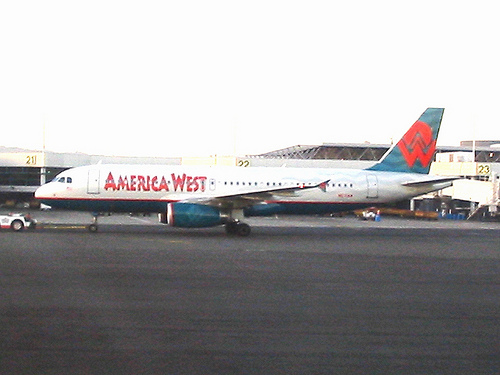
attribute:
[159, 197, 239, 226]
jet engine — blue, silver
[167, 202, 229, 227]
engine — blue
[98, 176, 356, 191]
windows — small, in row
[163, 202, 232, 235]
jet engine — large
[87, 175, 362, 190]
windows — in row , passenger's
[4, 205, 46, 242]
car — white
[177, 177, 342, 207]
wing — white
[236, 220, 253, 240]
tire — black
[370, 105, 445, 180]
tail — red, large, blue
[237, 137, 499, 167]
roof — metal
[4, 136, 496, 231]
terminal — airport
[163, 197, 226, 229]
engine — jet engine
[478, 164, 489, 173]
23 — black, gate number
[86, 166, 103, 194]
door — front door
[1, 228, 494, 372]
tarmac — black, airplane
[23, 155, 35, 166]
21 — black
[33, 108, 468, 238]
plane — side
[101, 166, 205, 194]
writing — red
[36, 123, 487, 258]
jet — small, passenger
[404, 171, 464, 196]
fin — tail 